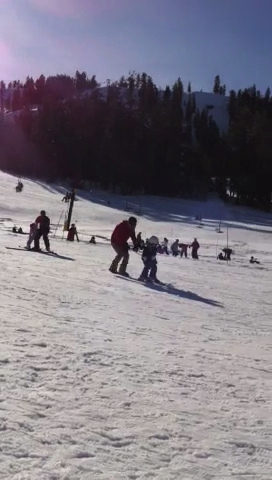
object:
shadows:
[109, 271, 223, 309]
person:
[248, 254, 260, 265]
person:
[170, 239, 179, 257]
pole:
[61, 186, 80, 228]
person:
[189, 237, 200, 260]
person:
[222, 247, 232, 261]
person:
[66, 222, 79, 242]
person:
[160, 237, 170, 255]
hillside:
[0, 70, 271, 480]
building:
[110, 85, 252, 203]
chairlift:
[15, 178, 24, 192]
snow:
[0, 80, 271, 480]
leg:
[42, 234, 50, 252]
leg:
[33, 231, 41, 247]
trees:
[0, 69, 272, 216]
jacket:
[110, 219, 136, 248]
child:
[139, 235, 161, 283]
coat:
[141, 238, 157, 264]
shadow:
[32, 179, 272, 237]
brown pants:
[111, 235, 130, 272]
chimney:
[117, 76, 129, 103]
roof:
[64, 71, 194, 115]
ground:
[0, 181, 272, 480]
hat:
[150, 235, 159, 245]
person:
[134, 231, 143, 252]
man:
[33, 208, 51, 251]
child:
[26, 218, 41, 251]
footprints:
[0, 325, 272, 480]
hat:
[129, 217, 138, 226]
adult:
[109, 215, 138, 276]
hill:
[0, 71, 272, 218]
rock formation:
[0, 71, 229, 184]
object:
[89, 236, 96, 245]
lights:
[225, 188, 239, 200]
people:
[14, 180, 23, 193]